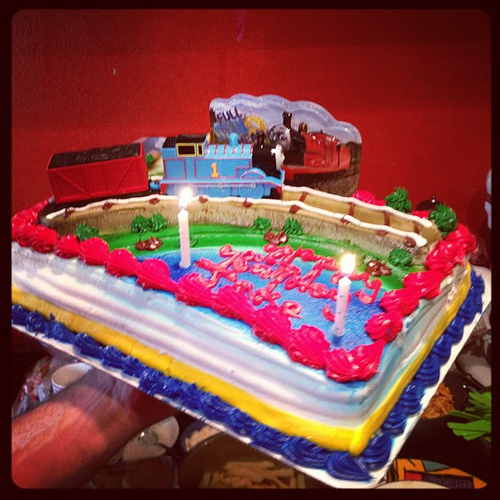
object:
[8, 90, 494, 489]
cake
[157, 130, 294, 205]
train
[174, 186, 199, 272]
candle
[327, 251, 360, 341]
candle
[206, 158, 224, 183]
number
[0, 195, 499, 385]
icing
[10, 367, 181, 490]
someone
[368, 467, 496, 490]
plate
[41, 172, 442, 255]
track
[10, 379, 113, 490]
arm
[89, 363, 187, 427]
hand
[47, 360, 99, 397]
cup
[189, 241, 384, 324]
writing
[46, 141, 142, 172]
coal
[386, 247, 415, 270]
trees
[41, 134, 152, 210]
car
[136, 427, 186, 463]
spoon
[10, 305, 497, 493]
table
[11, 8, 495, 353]
wall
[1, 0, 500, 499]
photo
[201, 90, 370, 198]
illustration